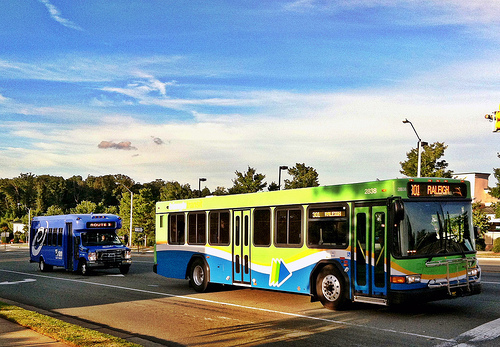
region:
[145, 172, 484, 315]
a big bus color green, blue and white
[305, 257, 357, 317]
front wheel of bus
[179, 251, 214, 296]
back wheel of bus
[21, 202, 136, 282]
a bus is color blue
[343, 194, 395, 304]
front door in front a bus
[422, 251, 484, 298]
a rail in front a bus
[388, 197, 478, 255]
glass window on bus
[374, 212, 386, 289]
glass window on bus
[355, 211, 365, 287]
glass window on bus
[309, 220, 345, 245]
glass window on bus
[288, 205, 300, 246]
glass window on bus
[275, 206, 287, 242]
glass window on bus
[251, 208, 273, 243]
glass window on bus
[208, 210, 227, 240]
glass window on bus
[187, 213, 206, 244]
glass window on bus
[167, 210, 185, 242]
glass window on bus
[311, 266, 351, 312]
a tire on the bus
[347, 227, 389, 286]
doors on the bus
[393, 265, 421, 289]
lights on the bus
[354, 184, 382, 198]
a number on the bus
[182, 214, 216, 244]
a window on a bus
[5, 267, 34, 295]
an arrow on the street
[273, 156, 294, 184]
a light above the street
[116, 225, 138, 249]
a mirror on the bus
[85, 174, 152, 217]
trees in the distance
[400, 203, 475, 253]
glass window on bus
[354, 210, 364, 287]
glass window on bus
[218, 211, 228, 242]
glass window on bus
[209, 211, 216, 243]
glass window on bus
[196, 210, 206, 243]
glass window on bus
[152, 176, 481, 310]
a green and blue public service bus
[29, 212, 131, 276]
a blue shuttle bus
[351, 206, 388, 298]
bus entry doors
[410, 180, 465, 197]
electronic bus destination sign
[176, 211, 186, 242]
bus has a window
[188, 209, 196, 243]
bus has a window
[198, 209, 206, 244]
bus has a window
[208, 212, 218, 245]
bus has a window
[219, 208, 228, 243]
bus has a window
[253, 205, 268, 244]
bus has a window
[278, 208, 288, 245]
bus has a window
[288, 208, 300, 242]
bus has a window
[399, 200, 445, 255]
bus has a window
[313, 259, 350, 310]
large black front tire with silver rim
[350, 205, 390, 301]
green and blue bus doors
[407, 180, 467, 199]
black bus led sign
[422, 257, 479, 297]
metal bike rack on front of bus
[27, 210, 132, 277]
blue passenger bus driving on a street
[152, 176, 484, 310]
large colorful mass transit bus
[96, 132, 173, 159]
group of dark clouds in the sky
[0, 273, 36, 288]
white arrow painted on street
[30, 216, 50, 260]
white swirl on side of bus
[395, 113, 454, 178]
metal street lamp behind bus